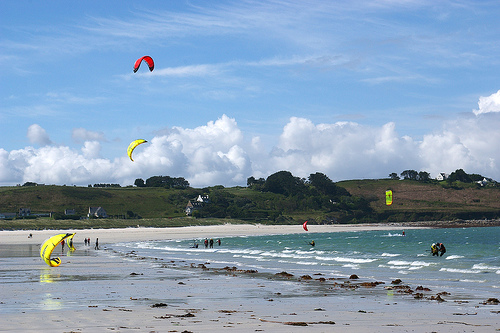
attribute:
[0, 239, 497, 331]
sand — wet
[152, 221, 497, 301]
ocean — blue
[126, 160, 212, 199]
trees — leafy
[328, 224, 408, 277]
wave — small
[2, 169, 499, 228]
hill — grassy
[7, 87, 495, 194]
clouds — white, puffy, low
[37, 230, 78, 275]
parasail — yellow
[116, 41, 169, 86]
kite — yellow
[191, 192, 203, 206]
house — distant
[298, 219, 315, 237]
kite — red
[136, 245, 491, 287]
waves — white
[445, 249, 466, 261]
cap — white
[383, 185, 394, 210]
sail — yellow 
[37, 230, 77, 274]
sail — yellow 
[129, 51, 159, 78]
sail — yellow 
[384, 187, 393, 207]
glider — yellow and green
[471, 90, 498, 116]
cloud — white 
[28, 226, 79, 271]
glider — yellow, blue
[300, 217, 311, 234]
sail — red 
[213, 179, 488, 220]
hill — covered , grassy 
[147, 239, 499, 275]
waves — white, crashed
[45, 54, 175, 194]
black glider — red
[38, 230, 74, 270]
parasail — yellow 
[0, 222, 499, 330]
beach — sandy 